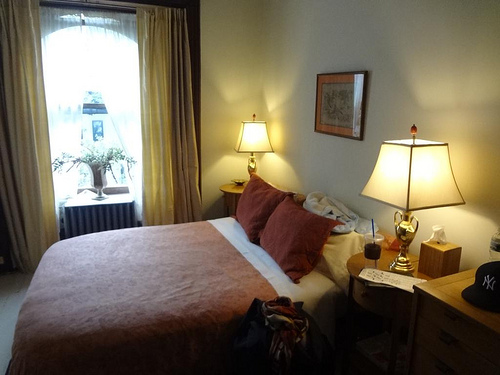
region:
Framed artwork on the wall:
[312, 70, 372, 145]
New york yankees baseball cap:
[468, 261, 496, 313]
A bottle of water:
[489, 226, 498, 271]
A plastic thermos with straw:
[364, 216, 382, 278]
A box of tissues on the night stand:
[422, 225, 463, 282]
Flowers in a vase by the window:
[51, 151, 139, 201]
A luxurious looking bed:
[32, 189, 358, 364]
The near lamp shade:
[368, 125, 471, 212]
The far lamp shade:
[232, 110, 272, 154]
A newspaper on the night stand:
[357, 264, 426, 295]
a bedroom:
[6, 64, 448, 367]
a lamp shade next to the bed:
[362, 117, 458, 282]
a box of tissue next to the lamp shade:
[414, 220, 461, 280]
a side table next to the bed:
[331, 242, 420, 373]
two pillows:
[231, 170, 331, 279]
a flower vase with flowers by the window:
[43, 121, 137, 209]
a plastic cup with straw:
[351, 211, 387, 271]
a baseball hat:
[456, 258, 499, 314]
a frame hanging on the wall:
[298, 53, 371, 150]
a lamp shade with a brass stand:
[221, 105, 273, 184]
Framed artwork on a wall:
[306, 55, 378, 144]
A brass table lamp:
[351, 118, 445, 298]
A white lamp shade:
[231, 114, 287, 160]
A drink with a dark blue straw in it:
[355, 210, 388, 269]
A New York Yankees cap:
[453, 252, 496, 321]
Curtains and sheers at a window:
[3, 1, 209, 218]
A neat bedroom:
[6, 80, 468, 367]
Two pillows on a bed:
[197, 170, 336, 282]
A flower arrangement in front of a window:
[55, 137, 142, 207]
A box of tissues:
[416, 220, 466, 287]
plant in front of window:
[48, 139, 139, 201]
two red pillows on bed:
[233, 171, 343, 287]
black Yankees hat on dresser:
[460, 261, 498, 314]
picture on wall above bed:
[312, 70, 368, 141]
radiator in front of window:
[61, 193, 137, 237]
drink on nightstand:
[361, 217, 384, 269]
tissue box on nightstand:
[416, 222, 466, 277]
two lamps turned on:
[233, 112, 470, 276]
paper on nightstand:
[355, 263, 426, 295]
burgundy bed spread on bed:
[6, 217, 277, 374]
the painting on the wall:
[308, 68, 379, 153]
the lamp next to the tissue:
[355, 105, 467, 282]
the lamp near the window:
[219, 107, 276, 188]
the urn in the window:
[83, 161, 124, 206]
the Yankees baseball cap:
[461, 255, 499, 317]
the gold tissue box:
[417, 223, 469, 278]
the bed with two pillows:
[4, 174, 394, 374]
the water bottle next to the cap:
[483, 220, 498, 267]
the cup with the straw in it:
[357, 233, 388, 271]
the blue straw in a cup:
[369, 218, 379, 239]